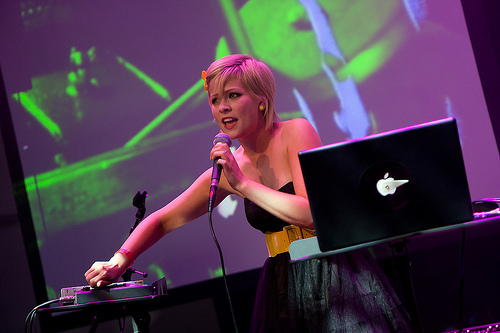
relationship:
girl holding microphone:
[81, 54, 411, 333] [207, 130, 238, 330]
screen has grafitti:
[0, 0, 499, 309] [9, 3, 429, 248]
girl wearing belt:
[81, 54, 411, 333] [262, 221, 317, 259]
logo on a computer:
[375, 173, 410, 197] [295, 112, 476, 252]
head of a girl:
[202, 51, 277, 144] [81, 50, 324, 290]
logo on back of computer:
[375, 173, 410, 197] [295, 112, 476, 252]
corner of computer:
[424, 110, 465, 148] [295, 112, 476, 252]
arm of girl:
[101, 167, 220, 261] [81, 50, 324, 290]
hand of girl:
[80, 258, 122, 288] [81, 50, 324, 290]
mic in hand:
[206, 132, 234, 212] [207, 141, 243, 188]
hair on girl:
[199, 51, 280, 129] [81, 50, 324, 290]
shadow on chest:
[249, 149, 281, 195] [227, 125, 291, 197]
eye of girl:
[224, 89, 241, 100] [81, 50, 324, 290]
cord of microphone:
[204, 194, 237, 330] [207, 126, 232, 200]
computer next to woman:
[295, 115, 476, 254] [80, 54, 422, 330]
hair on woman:
[199, 51, 280, 129] [80, 54, 422, 330]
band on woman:
[114, 248, 134, 263] [80, 54, 422, 330]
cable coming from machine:
[20, 291, 72, 330] [56, 265, 161, 308]